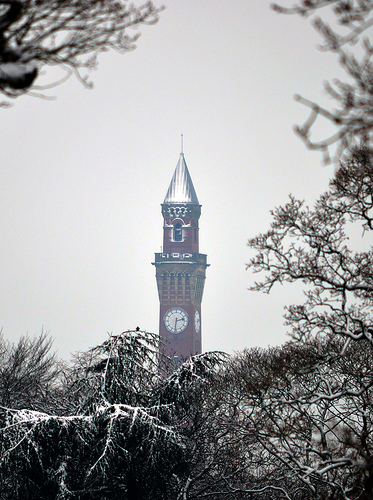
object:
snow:
[106, 418, 117, 433]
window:
[172, 220, 183, 243]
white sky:
[19, 137, 126, 303]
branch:
[329, 246, 366, 288]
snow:
[154, 418, 170, 433]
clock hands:
[174, 316, 184, 331]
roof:
[163, 152, 199, 205]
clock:
[163, 305, 189, 335]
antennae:
[179, 130, 183, 155]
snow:
[176, 368, 191, 394]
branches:
[36, 0, 78, 42]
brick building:
[150, 132, 210, 375]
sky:
[0, 0, 372, 360]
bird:
[134, 325, 140, 333]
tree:
[268, 1, 372, 177]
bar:
[180, 131, 183, 153]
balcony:
[151, 250, 212, 266]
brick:
[168, 241, 194, 252]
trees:
[187, 335, 373, 500]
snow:
[54, 402, 70, 424]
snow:
[338, 327, 363, 336]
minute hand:
[173, 316, 179, 331]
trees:
[0, 0, 166, 109]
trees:
[243, 142, 372, 344]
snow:
[112, 399, 141, 418]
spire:
[163, 132, 199, 204]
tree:
[0, 325, 230, 497]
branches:
[0, 434, 49, 499]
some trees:
[0, 325, 372, 498]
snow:
[165, 188, 187, 200]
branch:
[117, 330, 168, 348]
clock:
[194, 308, 201, 334]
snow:
[85, 450, 104, 469]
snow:
[9, 406, 45, 431]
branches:
[335, 321, 365, 373]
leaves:
[259, 371, 285, 385]